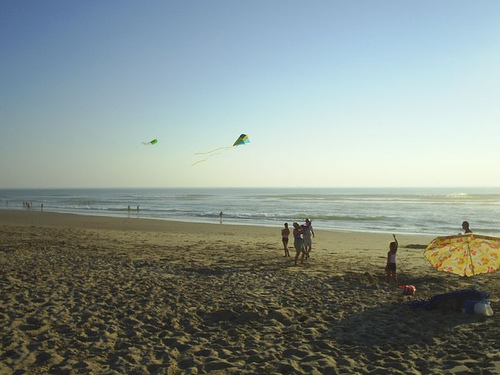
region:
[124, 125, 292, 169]
two kites in sky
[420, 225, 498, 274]
open umbrella in sand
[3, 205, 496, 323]
sand in front of ocean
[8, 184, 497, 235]
ocean water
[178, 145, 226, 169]
streaming tail of kite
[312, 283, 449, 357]
shadow on sand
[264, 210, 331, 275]
people standing on sand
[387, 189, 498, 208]
water wave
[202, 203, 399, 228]
long wave near shoreline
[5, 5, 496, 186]
blue sky getting lighter toward horizon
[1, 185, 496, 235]
wedge of gray ocean with low waves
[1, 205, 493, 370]
beach filled with depressions and bumps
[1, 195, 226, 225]
beach-goers along edge of beach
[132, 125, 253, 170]
flying kites and streamers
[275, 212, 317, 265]
people standing close together on beach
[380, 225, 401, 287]
child with an arm lifted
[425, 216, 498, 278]
person behind open umbrella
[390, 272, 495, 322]
bags left on top of sand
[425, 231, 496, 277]
red print on yellow background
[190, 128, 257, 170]
a blue and green kite in the air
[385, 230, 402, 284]
a person standing on the beach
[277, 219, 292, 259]
a person standing on the beach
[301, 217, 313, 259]
a person standing on the beach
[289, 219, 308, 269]
a person standing on the beach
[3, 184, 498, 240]
a large body of water near a beach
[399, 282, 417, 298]
a red bag on a beach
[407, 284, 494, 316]
a blue blanket on a beach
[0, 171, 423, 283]
people in the beach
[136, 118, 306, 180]
two kites in the blue sky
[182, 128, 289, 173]
a green kite with yellow tails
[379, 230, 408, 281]
a boy with right hand up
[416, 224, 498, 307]
an umbrella on the sand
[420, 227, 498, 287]
umbrella is color yellow and red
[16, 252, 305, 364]
footsteps on the sand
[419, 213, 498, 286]
a person behind an umbrella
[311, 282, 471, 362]
a shadow on the sand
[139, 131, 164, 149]
a green kite in the sky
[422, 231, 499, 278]
an umbrella sitting on the beach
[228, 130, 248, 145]
a big kite flying in the air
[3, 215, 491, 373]
the beach that the people are standing on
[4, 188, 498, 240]
the calm water of the ocean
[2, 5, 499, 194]
the clear blue sky above the beach and ocean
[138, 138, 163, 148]
another cloud in the sky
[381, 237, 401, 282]
a kid standing on the beach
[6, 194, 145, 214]
more people standing around on the beach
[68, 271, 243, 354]
footprints on the beach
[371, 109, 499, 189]
the sunny part of the sky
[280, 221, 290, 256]
A person is standing up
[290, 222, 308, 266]
A person is standing up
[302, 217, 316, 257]
A person is standing up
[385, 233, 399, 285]
A person is standing up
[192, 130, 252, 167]
A kite is flying in the sky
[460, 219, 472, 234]
A person is standing up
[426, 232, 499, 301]
An umbrella used for shade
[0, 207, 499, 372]
A beach with lots of sand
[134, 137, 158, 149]
A kite flying in the sky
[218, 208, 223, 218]
A person playing in the water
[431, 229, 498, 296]
a large open umbrella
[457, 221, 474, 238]
a person is standing up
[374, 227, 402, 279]
a person is standing up